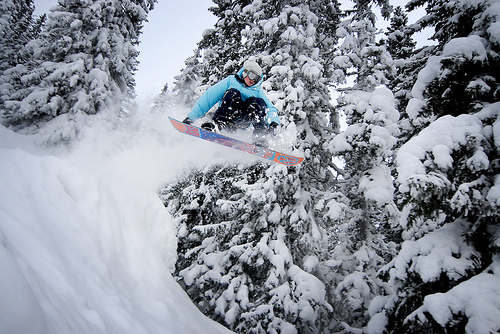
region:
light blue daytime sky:
[148, 10, 208, 67]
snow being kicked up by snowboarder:
[92, 129, 153, 193]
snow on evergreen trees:
[250, 215, 348, 279]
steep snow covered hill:
[55, 250, 117, 308]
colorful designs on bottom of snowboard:
[178, 124, 304, 164]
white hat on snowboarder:
[238, 60, 266, 75]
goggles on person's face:
[242, 67, 264, 83]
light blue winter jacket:
[195, 75, 283, 125]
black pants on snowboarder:
[214, 86, 266, 144]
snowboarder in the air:
[175, 62, 300, 168]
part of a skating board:
[216, 122, 258, 162]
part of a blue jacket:
[196, 82, 213, 112]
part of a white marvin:
[249, 58, 262, 73]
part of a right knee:
[223, 85, 240, 110]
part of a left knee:
[255, 102, 268, 119]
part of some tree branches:
[221, 233, 276, 293]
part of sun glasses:
[246, 68, 258, 83]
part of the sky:
[143, 8, 183, 58]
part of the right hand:
[179, 115, 190, 124]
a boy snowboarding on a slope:
[165, 56, 305, 167]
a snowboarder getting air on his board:
[161, 56, 307, 167]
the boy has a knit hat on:
[237, 58, 262, 74]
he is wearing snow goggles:
[237, 65, 259, 85]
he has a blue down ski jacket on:
[180, 75, 280, 125]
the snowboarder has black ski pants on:
[216, 87, 267, 134]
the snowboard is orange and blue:
[165, 113, 305, 169]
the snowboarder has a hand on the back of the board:
[167, 60, 262, 150]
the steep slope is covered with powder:
[10, 100, 238, 331]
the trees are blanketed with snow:
[9, 2, 493, 332]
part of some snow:
[36, 244, 125, 320]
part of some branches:
[267, 250, 312, 304]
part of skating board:
[246, 143, 281, 167]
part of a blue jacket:
[201, 97, 218, 113]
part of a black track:
[228, 96, 243, 114]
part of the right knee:
[223, 86, 237, 102]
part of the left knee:
[250, 97, 267, 114]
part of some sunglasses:
[248, 73, 260, 82]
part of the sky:
[164, 2, 198, 43]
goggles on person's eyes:
[240, 65, 260, 80]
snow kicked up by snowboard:
[97, 136, 196, 193]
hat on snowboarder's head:
[242, 53, 271, 73]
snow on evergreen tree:
[392, 109, 466, 185]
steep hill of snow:
[42, 219, 121, 304]